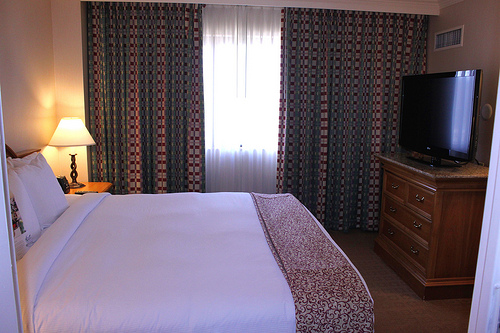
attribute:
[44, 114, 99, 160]
lamp — on, brown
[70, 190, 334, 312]
bed — white, made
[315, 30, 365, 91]
curtain — brown, green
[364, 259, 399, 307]
floor — brown, black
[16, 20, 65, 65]
wall — white, brown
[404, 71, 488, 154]
tv — black, hd, off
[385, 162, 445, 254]
dresser — brown, wood, closed